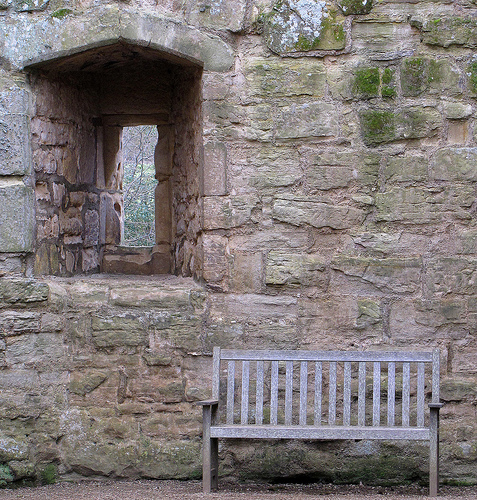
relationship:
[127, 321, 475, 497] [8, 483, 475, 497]
bench on ground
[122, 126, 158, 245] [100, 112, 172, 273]
trees behind window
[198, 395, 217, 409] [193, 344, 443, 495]
arm rest on bench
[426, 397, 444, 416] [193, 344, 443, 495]
arm rest on bench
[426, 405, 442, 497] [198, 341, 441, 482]
leg on bench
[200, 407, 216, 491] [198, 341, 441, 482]
leg on bench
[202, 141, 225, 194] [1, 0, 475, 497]
brick on building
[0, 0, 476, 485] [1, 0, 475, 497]
wall of building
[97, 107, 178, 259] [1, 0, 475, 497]
window in a building